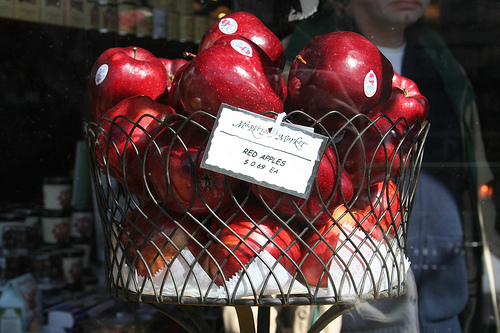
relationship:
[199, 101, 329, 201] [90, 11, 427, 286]
tag on apples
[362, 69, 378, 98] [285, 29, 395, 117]
sticker on apple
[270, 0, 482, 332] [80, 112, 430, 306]
man standing behind basket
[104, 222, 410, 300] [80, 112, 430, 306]
lining sitting in basket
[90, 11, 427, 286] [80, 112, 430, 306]
apples displayed in basket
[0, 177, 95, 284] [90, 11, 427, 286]
items selling behind apples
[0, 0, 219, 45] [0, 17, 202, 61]
items sitting on shelf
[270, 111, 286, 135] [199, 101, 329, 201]
strap holding tag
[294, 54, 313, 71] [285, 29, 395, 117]
stem attached to apple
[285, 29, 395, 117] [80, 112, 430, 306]
apple sitting in basket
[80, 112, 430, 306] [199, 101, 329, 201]
basket has tag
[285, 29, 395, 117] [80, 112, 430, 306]
apple in basket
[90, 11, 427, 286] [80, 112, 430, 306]
apples sitting in basket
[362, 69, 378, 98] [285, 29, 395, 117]
sticker stuck on apple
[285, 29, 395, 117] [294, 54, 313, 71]
apple has stem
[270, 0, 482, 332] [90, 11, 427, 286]
man behind apples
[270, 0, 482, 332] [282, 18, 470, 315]
man wearing jacket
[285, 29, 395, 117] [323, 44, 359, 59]
apple has part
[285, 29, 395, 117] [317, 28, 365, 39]
apple has edge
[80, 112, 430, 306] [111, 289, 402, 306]
basket has bottom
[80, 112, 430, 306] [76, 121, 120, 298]
basket has side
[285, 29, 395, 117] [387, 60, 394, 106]
apple has side